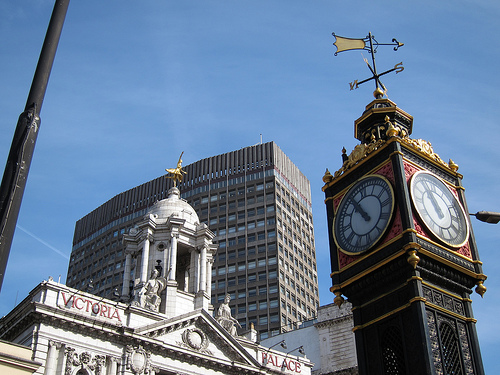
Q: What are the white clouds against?
A: The blue sky.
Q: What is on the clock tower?
A: Wind directional.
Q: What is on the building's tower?
A: A clock.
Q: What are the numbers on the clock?
A: Roman numeral.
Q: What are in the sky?
A: Clouds.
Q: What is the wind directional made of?
A: Gold.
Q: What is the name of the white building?
A: Victoria Palace.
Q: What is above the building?
A: Sky.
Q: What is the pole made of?
A: Metal.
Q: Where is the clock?
A: On tower.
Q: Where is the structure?
A: On palace.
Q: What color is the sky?
A: Blue.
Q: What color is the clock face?
A: White.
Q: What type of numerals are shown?
A: Roman.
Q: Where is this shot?
A: Street.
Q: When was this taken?
A: Daytime.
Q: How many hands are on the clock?
A: 2.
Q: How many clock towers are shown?
A: 1.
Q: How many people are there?
A: 0.